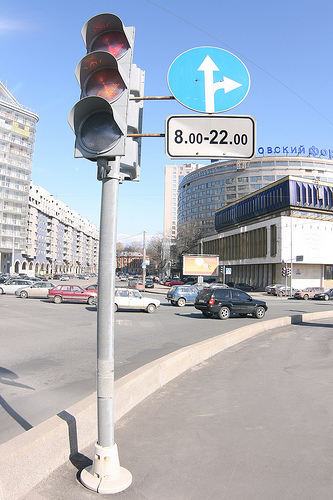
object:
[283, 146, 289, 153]
letter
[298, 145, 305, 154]
letter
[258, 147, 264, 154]
letter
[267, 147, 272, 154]
letter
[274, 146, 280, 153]
letter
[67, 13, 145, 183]
traffic light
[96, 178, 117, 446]
pole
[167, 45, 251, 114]
sign board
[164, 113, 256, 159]
sign board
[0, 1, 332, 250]
sky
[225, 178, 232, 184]
window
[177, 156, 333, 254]
building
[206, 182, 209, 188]
window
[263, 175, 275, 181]
window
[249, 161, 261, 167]
window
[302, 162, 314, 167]
window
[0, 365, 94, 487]
shadow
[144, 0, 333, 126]
power line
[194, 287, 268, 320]
suv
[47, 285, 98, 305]
car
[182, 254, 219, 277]
billboard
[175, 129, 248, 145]
times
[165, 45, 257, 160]
traffic information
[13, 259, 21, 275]
arch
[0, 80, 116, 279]
building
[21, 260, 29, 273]
arch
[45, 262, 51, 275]
arch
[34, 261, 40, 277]
arch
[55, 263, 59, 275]
arch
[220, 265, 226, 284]
street light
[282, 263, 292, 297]
street light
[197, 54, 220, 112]
arrow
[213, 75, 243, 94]
arrow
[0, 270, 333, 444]
parking lot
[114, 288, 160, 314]
car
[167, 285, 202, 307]
car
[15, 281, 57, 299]
car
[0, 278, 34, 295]
car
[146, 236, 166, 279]
tree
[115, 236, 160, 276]
distance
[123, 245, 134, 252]
tree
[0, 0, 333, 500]
foreground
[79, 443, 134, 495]
base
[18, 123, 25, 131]
balcony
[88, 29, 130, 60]
light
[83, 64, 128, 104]
light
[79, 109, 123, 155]
light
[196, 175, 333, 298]
building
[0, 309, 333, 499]
curve